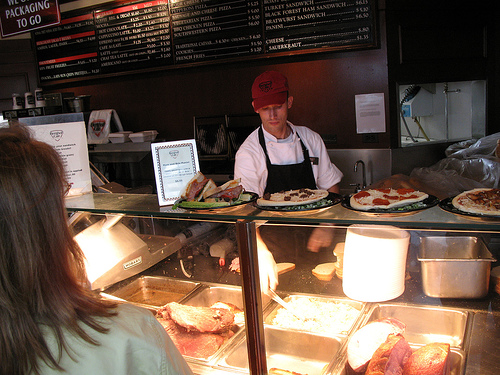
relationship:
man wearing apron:
[222, 68, 347, 193] [259, 132, 315, 197]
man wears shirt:
[222, 68, 347, 193] [220, 125, 342, 209]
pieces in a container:
[348, 321, 473, 372] [323, 298, 478, 373]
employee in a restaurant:
[228, 66, 347, 266] [5, 2, 492, 371]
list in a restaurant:
[19, 118, 95, 201] [5, 2, 492, 371]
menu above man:
[0, 6, 384, 54] [222, 68, 347, 193]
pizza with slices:
[351, 185, 377, 206] [369, 193, 389, 206]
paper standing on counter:
[149, 137, 206, 209] [97, 185, 232, 232]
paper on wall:
[352, 90, 387, 137] [290, 69, 387, 130]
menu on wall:
[0, 6, 384, 54] [40, 27, 392, 106]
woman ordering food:
[2, 123, 193, 371] [183, 172, 312, 210]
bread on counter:
[309, 254, 341, 280] [265, 226, 396, 284]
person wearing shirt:
[244, 68, 338, 208] [232, 123, 344, 191]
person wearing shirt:
[232, 70, 339, 198] [233, 125, 342, 196]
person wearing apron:
[244, 68, 338, 208] [258, 129, 320, 204]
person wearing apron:
[232, 70, 339, 198] [259, 136, 313, 202]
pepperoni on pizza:
[357, 184, 416, 209] [351, 185, 377, 206]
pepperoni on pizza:
[381, 186, 404, 207] [356, 181, 422, 208]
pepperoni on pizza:
[357, 184, 416, 209] [349, 171, 435, 211]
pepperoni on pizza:
[357, 184, 416, 209] [348, 176, 416, 211]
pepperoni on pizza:
[381, 186, 404, 207] [356, 175, 413, 211]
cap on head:
[251, 69, 288, 110] [236, 95, 307, 141]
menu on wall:
[116, 8, 200, 55] [287, 40, 381, 123]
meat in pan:
[362, 322, 424, 372] [384, 306, 439, 329]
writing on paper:
[159, 143, 197, 193] [149, 137, 206, 209]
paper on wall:
[352, 90, 387, 137] [284, 4, 397, 141]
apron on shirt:
[259, 132, 315, 197] [229, 114, 346, 204]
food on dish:
[409, 341, 448, 371] [366, 329, 458, 373]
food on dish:
[367, 329, 411, 373] [363, 327, 463, 373]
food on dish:
[164, 298, 234, 337] [163, 295, 234, 335]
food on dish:
[194, 172, 222, 202] [181, 172, 241, 213]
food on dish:
[194, 172, 222, 202] [177, 173, 257, 209]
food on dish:
[194, 172, 222, 202] [180, 170, 249, 210]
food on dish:
[349, 180, 373, 207] [346, 180, 429, 213]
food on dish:
[349, 180, 373, 207] [347, 180, 430, 217]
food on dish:
[349, 180, 373, 207] [341, 176, 430, 218]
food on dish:
[261, 186, 317, 207] [255, 181, 332, 215]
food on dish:
[194, 172, 222, 202] [172, 167, 249, 214]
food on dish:
[194, 172, 222, 202] [176, 176, 248, 211]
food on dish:
[457, 182, 491, 216] [449, 177, 499, 221]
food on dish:
[349, 180, 373, 207] [347, 170, 430, 217]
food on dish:
[349, 180, 373, 207] [352, 176, 430, 216]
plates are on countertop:
[172, 175, 494, 229] [13, 175, 494, 365]